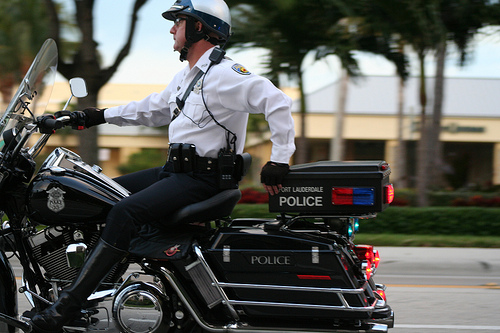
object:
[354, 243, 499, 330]
ground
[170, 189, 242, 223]
seat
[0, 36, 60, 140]
windshield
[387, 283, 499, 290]
line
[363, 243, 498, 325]
street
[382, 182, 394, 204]
tail light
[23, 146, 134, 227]
gas tank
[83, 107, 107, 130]
hand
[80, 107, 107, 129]
glove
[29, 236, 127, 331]
boot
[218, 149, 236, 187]
walky talky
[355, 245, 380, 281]
light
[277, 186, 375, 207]
police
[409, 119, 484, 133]
sign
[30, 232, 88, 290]
engine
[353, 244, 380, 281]
taillight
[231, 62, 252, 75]
patch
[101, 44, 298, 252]
uniform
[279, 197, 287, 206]
letter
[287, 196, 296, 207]
letter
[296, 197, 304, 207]
letter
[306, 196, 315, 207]
letter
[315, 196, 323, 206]
letter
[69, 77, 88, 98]
mirror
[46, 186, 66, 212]
logo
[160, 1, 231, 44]
helmet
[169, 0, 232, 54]
head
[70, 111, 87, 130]
handle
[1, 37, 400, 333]
motorcycle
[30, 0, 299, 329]
man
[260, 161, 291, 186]
glove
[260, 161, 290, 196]
hand